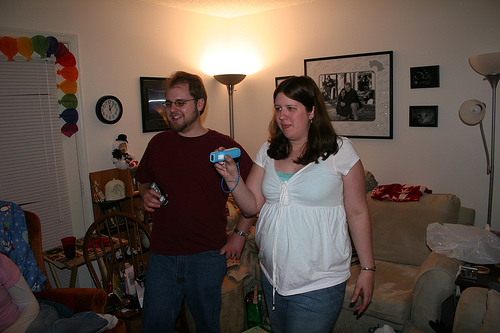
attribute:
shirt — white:
[255, 148, 354, 292]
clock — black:
[95, 95, 126, 126]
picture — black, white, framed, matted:
[307, 56, 395, 139]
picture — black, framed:
[408, 66, 441, 89]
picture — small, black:
[410, 105, 440, 127]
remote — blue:
[207, 151, 243, 161]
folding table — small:
[49, 235, 124, 262]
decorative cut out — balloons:
[3, 36, 75, 67]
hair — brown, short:
[175, 71, 205, 98]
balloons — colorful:
[57, 57, 83, 136]